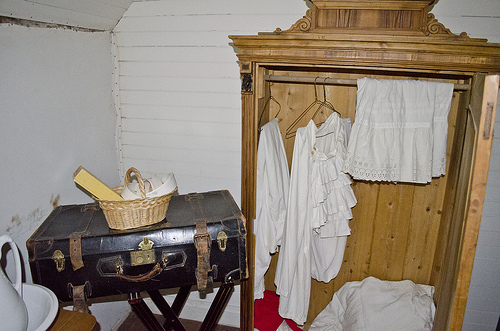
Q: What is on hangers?
A: Clothing.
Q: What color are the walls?
A: White.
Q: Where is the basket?
A: On the suitcase.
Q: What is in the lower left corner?
A: Pitcher.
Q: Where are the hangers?
A: Hanging on a rod.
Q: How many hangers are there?
A: 3.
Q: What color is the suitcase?
A: Black.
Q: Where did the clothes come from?
A: Suitcase.